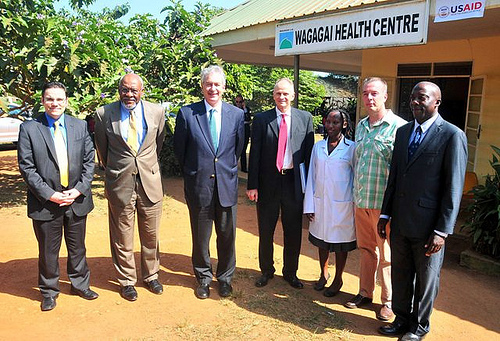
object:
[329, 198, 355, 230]
pocket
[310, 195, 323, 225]
pocket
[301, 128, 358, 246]
coat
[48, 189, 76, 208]
hands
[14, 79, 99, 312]
man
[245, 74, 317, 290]
man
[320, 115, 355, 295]
skin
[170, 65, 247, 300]
man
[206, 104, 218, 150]
tie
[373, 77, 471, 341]
person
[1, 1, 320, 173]
trees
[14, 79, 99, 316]
man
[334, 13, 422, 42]
health centre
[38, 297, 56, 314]
shoe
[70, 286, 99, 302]
shoe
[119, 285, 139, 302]
shoe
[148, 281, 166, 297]
shoe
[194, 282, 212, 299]
shoe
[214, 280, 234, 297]
shoe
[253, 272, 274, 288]
shoe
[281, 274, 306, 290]
shoe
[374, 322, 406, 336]
shoe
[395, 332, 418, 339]
shoe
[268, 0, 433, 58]
sign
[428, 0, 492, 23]
sign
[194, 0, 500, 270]
building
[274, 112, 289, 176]
tie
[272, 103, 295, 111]
neck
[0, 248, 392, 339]
shadow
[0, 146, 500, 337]
dirt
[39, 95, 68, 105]
glasses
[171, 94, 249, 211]
jacket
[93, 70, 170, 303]
man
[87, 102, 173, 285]
suit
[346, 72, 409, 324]
person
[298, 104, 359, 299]
person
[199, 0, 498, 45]
roof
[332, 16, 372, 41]
word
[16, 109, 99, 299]
suit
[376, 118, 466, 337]
suit